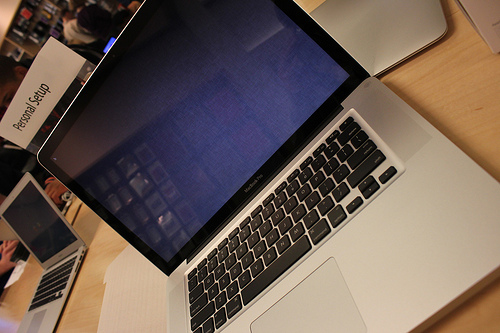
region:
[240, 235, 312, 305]
a black keyboard spacebar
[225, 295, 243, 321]
a black keyboard command key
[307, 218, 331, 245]
a black keyboard command key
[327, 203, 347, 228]
a black keyboard option key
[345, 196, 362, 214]
a black keyboard left arrow key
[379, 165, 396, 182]
a black keyboard right arrow key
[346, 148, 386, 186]
a black keyboard shift key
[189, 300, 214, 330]
a black keyboard shift key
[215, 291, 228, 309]
a black keyboard z key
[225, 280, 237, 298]
a black keyboard x key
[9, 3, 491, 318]
laptop on a surface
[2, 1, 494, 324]
laptop on a wood grain surface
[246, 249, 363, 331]
touch pad on a laptop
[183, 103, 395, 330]
keyboard on a laptop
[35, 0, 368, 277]
screen of a laptop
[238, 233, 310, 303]
space bar of the keyboard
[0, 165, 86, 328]
laptop on the left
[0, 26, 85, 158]
a sign with a bit of information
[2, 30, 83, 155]
a sign with a bite of information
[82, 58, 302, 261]
reflection in the screen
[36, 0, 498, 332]
an Apple MacBook Pro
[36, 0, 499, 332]
an open laptop computer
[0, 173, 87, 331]
an open laptop computer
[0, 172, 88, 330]
an Apple MacBook Air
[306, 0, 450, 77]
a closed laptop computer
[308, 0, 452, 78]
a closed Apple MacBook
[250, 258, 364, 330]
a computer track pad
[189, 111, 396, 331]
a black computer keyboard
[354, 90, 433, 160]
a computer speaker grill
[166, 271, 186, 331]
a computer speaker grill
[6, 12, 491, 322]
laptops on display on flat surface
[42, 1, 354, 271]
black frame around blue screen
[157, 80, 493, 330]
black keypad in gray case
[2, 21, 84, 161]
white sign over open laptop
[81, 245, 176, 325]
paper with tabbed corner on wood surface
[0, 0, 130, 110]
people looking at display case against wall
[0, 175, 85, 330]
open laptop with black screen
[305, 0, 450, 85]
curved metal panel behind laptop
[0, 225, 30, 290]
hand on top of black object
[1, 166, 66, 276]
hands on either side of laptop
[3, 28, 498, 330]
Laptops on the table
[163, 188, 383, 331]
Keyboard is black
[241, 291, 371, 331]
The touch pad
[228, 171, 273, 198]
Company logo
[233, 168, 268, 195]
"MacBook Pro"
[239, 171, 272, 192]
The letters are silver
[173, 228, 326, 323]
Letters are white on the keyboard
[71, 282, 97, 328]
Table is made of wood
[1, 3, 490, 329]
This is an apple store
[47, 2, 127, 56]
People in the back